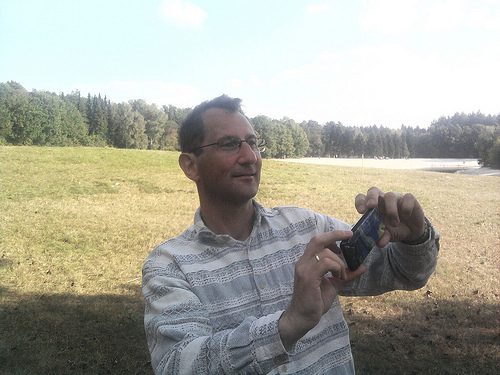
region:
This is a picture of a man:
[178, 107, 375, 311]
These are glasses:
[200, 140, 267, 149]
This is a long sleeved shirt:
[166, 222, 312, 366]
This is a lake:
[334, 144, 478, 232]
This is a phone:
[325, 204, 425, 286]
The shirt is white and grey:
[175, 209, 263, 356]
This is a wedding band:
[300, 245, 322, 276]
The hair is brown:
[140, 116, 267, 173]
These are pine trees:
[34, 86, 127, 227]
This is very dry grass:
[73, 188, 124, 267]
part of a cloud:
[328, 32, 378, 89]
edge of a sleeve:
[252, 303, 287, 360]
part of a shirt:
[211, 279, 243, 336]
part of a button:
[254, 278, 279, 324]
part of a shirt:
[186, 305, 226, 356]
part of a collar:
[213, 239, 243, 267]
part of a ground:
[92, 228, 137, 285]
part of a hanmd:
[303, 272, 313, 302]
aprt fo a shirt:
[208, 265, 224, 295]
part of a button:
[243, 249, 277, 289]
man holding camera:
[122, 87, 459, 372]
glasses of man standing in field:
[183, 130, 258, 157]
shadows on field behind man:
[20, 272, 493, 374]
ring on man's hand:
[311, 251, 323, 264]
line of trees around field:
[0, 85, 489, 154]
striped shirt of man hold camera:
[137, 207, 433, 372]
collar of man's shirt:
[182, 202, 279, 244]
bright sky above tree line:
[4, 7, 499, 112]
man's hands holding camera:
[270, 182, 426, 316]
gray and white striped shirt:
[134, 205, 369, 373]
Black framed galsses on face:
[171, 120, 275, 165]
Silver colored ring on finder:
[310, 218, 331, 283]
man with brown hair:
[146, 72, 263, 234]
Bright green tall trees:
[1, 82, 56, 145]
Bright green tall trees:
[70, 81, 130, 151]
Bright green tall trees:
[124, 94, 173, 151]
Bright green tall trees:
[257, 110, 290, 169]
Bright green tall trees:
[288, 115, 332, 158]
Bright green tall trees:
[340, 119, 385, 156]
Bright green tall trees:
[417, 122, 497, 173]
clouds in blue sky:
[0, 4, 497, 130]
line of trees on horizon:
[1, 79, 498, 159]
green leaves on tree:
[17, 93, 84, 143]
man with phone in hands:
[145, 93, 437, 372]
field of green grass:
[0, 144, 499, 374]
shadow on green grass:
[0, 283, 498, 373]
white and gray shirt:
[142, 202, 439, 374]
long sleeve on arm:
[138, 256, 294, 373]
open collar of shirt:
[192, 200, 276, 247]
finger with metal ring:
[297, 230, 350, 280]